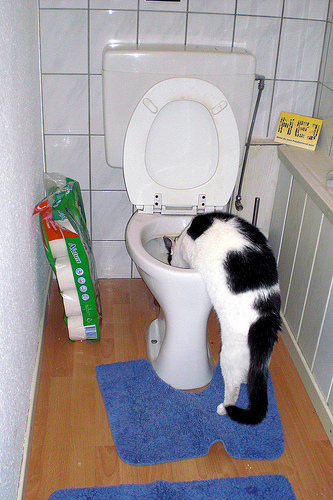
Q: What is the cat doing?
A: Drinking.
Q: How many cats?
A: One.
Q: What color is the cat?
A: Black and white.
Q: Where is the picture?
A: Bathroom.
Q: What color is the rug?
A: Blue.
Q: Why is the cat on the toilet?
A: To get water.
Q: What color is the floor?
A: Brown.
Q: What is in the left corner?
A: Toilet paper.